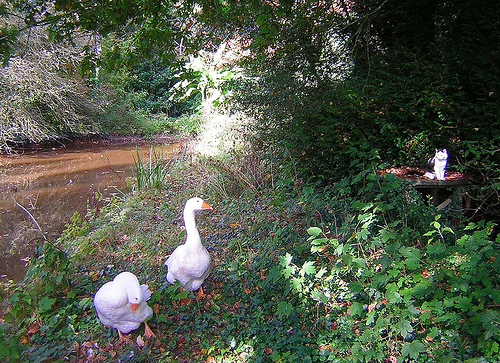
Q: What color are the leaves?
A: Green.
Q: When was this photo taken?
A: In the daytime.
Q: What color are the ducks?
A: White.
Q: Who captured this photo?
A: A photographer.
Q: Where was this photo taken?
A: By a lake.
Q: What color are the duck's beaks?
A: Orange.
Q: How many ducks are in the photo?
A: Two.